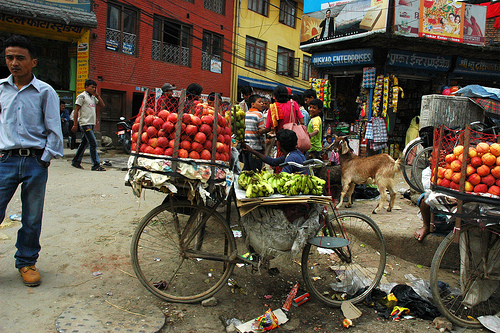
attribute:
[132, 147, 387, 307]
bicycle — fruit stand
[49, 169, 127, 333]
road — dirt path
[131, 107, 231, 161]
apples — red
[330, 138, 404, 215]
goat — brown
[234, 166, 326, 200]
bananas — sitting, green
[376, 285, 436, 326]
trash bag — black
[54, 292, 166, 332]
manhole cover — round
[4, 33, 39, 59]
mans hair — black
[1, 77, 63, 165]
shirt — blue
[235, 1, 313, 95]
building — yellow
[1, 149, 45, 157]
belt — black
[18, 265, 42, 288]
boots — brown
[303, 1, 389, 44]
signs — billboards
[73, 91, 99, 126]
shirt — white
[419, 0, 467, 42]
sign — multi colored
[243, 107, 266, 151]
shirt — striped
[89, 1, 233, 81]
building — painted red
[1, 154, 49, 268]
jeans — blue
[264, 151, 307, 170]
shirt — denim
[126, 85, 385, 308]
bicycle — fruit cart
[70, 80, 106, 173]
man — walking